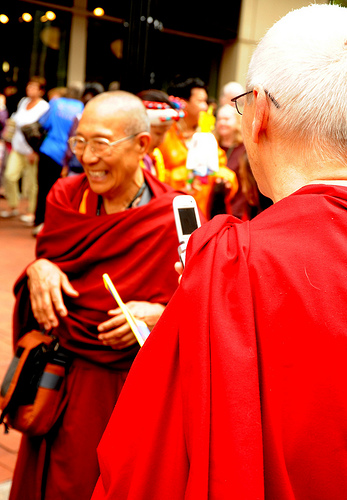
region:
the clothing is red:
[121, 256, 254, 498]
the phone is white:
[154, 183, 227, 239]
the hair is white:
[252, 5, 344, 128]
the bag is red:
[5, 336, 64, 422]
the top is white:
[17, 101, 46, 154]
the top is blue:
[42, 103, 74, 162]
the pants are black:
[35, 157, 48, 223]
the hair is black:
[168, 75, 206, 96]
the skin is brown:
[248, 145, 346, 175]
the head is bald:
[88, 96, 152, 140]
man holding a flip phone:
[160, 189, 218, 287]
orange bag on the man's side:
[0, 322, 88, 440]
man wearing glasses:
[225, 89, 288, 117]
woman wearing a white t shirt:
[14, 79, 60, 155]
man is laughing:
[60, 85, 161, 206]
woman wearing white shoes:
[0, 203, 39, 227]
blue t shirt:
[39, 97, 86, 165]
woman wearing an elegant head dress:
[129, 86, 206, 133]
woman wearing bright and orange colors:
[163, 67, 244, 224]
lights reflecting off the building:
[0, 8, 127, 83]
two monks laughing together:
[9, 54, 343, 484]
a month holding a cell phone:
[166, 20, 325, 316]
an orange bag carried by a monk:
[2, 331, 85, 434]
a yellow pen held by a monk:
[103, 272, 150, 342]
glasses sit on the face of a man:
[60, 80, 156, 211]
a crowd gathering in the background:
[145, 89, 238, 172]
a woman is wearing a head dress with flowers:
[151, 85, 186, 131]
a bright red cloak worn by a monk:
[166, 236, 328, 428]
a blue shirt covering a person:
[36, 87, 69, 168]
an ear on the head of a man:
[250, 87, 284, 149]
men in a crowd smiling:
[40, 33, 316, 467]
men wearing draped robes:
[13, 51, 312, 488]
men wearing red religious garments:
[32, 101, 322, 469]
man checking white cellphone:
[149, 15, 332, 313]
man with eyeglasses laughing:
[50, 69, 151, 210]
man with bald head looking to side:
[30, 71, 164, 202]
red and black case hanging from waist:
[0, 292, 87, 458]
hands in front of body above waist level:
[17, 252, 162, 346]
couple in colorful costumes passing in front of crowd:
[138, 71, 227, 212]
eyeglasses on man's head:
[218, 83, 296, 118]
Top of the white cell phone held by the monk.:
[172, 196, 202, 239]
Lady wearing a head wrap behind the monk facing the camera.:
[142, 92, 185, 131]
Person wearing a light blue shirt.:
[40, 87, 81, 161]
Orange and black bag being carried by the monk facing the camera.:
[8, 320, 68, 439]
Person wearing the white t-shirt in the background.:
[13, 88, 49, 154]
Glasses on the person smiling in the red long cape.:
[69, 126, 118, 155]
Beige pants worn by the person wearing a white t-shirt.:
[9, 151, 35, 213]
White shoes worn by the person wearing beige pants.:
[2, 206, 36, 228]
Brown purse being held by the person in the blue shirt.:
[26, 117, 38, 151]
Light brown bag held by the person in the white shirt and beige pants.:
[2, 116, 16, 141]